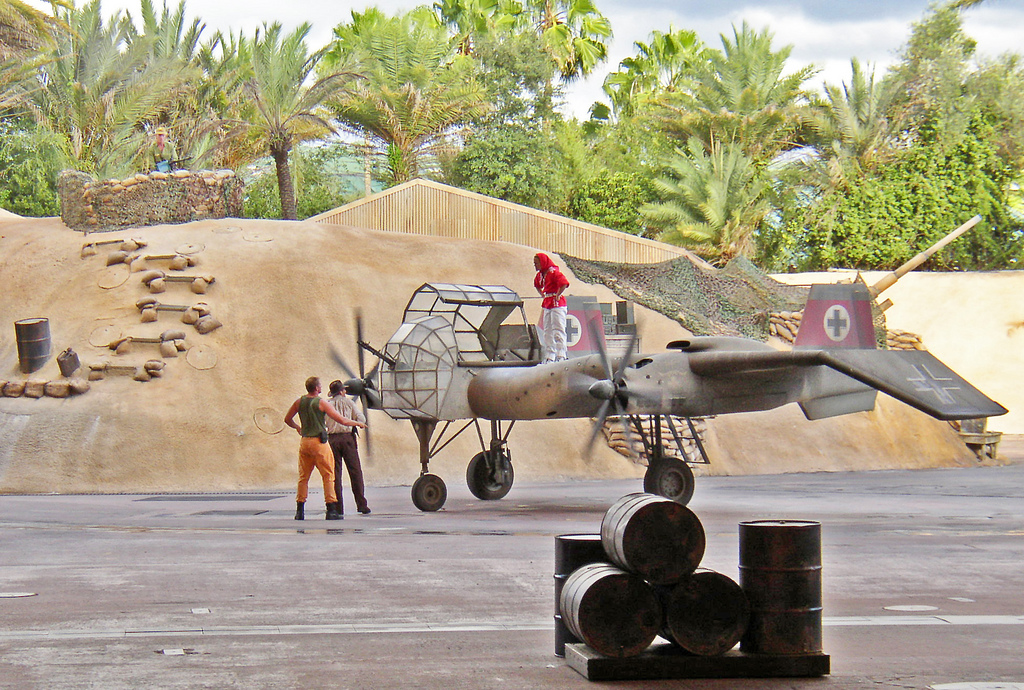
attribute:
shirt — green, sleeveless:
[296, 387, 327, 437]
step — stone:
[2, 374, 93, 398]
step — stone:
[76, 351, 167, 382]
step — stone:
[102, 320, 195, 359]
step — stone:
[136, 296, 227, 335]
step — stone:
[140, 264, 220, 293]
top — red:
[529, 248, 575, 303]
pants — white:
[524, 295, 576, 367]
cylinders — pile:
[552, 481, 853, 683]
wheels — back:
[460, 438, 709, 501]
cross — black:
[820, 289, 862, 350]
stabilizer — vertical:
[790, 261, 899, 352]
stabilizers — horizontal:
[673, 314, 1002, 429]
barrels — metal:
[567, 482, 745, 642]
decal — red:
[818, 296, 855, 340]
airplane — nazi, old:
[345, 275, 1011, 451]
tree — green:
[631, 162, 973, 353]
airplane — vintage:
[328, 238, 992, 515]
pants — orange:
[293, 439, 345, 509]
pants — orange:
[287, 433, 348, 505]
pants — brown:
[315, 430, 370, 517]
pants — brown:
[323, 431, 378, 511]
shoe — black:
[323, 506, 356, 526]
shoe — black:
[287, 506, 309, 526]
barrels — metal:
[543, 485, 842, 656]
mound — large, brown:
[4, 199, 992, 498]